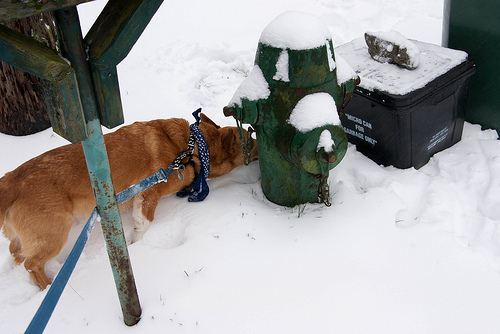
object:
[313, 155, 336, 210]
chain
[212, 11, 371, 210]
hydrant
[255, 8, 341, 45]
snow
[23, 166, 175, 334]
leash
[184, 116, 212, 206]
collar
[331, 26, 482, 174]
box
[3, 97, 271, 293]
dog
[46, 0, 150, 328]
posts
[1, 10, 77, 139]
stump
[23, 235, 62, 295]
legs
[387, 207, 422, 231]
footprints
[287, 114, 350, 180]
attachment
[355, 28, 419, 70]
rock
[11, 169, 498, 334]
snow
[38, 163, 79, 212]
fur